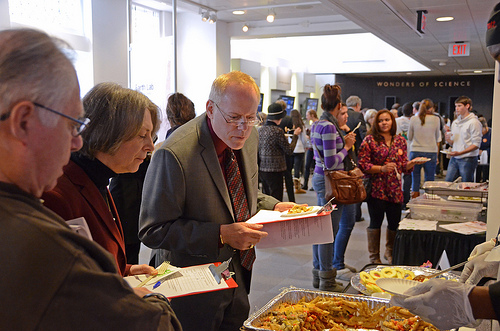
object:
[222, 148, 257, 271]
tie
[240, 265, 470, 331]
buffet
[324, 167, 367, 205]
brown bag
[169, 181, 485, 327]
buffett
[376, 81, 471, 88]
sign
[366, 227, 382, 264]
boot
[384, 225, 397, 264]
boot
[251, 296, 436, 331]
food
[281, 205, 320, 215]
plate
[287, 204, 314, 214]
food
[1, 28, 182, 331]
man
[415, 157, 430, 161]
food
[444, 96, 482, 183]
man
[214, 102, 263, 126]
eyeglasses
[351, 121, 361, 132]
spoon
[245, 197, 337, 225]
clip board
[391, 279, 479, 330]
hand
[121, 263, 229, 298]
paper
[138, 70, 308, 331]
guy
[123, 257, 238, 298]
clipboard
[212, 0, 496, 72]
ceiling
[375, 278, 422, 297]
paper plate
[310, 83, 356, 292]
people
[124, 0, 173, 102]
window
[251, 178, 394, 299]
floor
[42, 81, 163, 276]
lady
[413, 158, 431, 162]
plate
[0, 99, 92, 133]
glasses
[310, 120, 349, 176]
sweater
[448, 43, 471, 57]
exit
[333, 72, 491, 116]
wall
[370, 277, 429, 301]
table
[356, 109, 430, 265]
person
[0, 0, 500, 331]
room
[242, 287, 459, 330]
tray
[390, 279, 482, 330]
glove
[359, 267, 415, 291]
circles